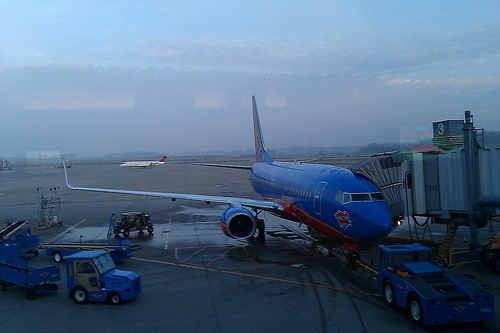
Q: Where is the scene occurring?
A: An airport.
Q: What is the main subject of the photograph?
A: Airplane.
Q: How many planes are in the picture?
A: 2.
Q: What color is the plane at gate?
A: Blue.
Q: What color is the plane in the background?
A: White.